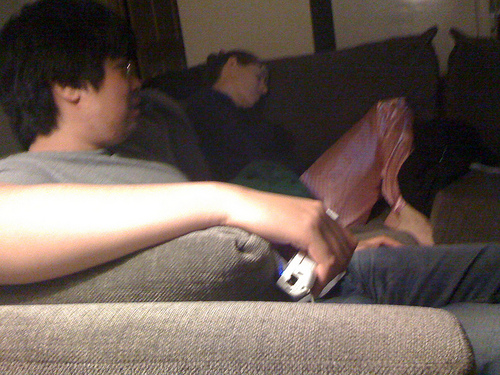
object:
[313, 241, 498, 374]
jeans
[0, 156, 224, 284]
arm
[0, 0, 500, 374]
man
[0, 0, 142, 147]
head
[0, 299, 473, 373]
arm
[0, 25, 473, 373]
couch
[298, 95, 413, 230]
pants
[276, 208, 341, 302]
controller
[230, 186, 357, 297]
hand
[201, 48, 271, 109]
head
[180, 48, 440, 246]
woman